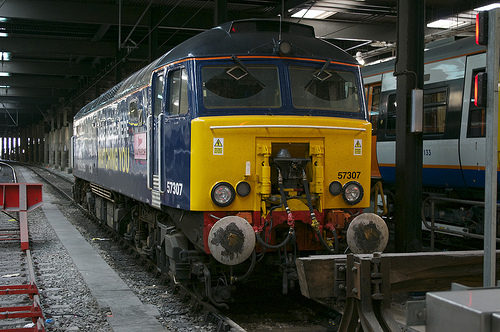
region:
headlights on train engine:
[201, 179, 371, 209]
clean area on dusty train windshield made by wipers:
[201, 65, 268, 102]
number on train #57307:
[333, 168, 362, 180]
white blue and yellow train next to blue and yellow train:
[356, 30, 498, 250]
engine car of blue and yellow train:
[62, 23, 397, 318]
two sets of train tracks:
[1, 152, 369, 329]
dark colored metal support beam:
[390, 2, 428, 250]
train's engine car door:
[139, 65, 171, 208]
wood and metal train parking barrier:
[290, 243, 499, 328]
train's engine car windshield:
[193, 49, 368, 120]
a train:
[172, 42, 373, 216]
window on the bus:
[160, 75, 187, 110]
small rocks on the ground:
[38, 253, 85, 329]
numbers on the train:
[336, 169, 362, 181]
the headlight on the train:
[207, 180, 234, 205]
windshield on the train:
[202, 64, 363, 111]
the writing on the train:
[82, 145, 137, 176]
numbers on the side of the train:
[159, 182, 193, 197]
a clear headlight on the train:
[341, 184, 363, 201]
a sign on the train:
[132, 134, 146, 158]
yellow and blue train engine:
[69, 17, 374, 301]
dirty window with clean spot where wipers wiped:
[287, 65, 363, 115]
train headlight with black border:
[211, 181, 237, 206]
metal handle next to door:
[156, 111, 166, 196]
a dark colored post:
[389, 15, 434, 265]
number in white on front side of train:
[163, 176, 188, 197]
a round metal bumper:
[204, 212, 255, 262]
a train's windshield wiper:
[230, 57, 265, 90]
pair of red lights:
[469, 6, 489, 108]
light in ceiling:
[289, 10, 337, 20]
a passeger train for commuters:
[8, 2, 437, 298]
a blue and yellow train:
[47, 75, 364, 229]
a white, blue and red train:
[367, 34, 493, 215]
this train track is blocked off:
[2, 166, 99, 331]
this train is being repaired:
[57, 160, 379, 312]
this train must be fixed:
[46, 185, 235, 298]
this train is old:
[172, 46, 379, 128]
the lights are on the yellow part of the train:
[172, 125, 390, 231]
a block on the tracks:
[295, 233, 477, 330]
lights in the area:
[279, 2, 477, 60]